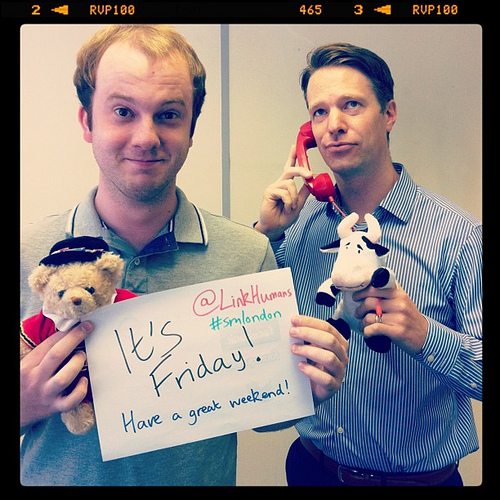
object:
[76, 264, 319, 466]
paper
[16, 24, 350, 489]
man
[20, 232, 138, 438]
bear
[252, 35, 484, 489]
man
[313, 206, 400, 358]
cow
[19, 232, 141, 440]
costume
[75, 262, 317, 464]
sign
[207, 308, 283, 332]
hash tags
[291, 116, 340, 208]
phone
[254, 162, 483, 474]
shirt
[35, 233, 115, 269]
cap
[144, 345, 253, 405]
words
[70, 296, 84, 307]
nose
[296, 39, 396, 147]
hair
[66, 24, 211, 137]
hair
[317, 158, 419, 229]
collar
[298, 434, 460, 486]
belt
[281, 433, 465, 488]
pants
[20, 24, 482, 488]
wall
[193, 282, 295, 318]
twitter name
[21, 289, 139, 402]
jacket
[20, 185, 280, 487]
polo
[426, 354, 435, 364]
button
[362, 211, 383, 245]
horns